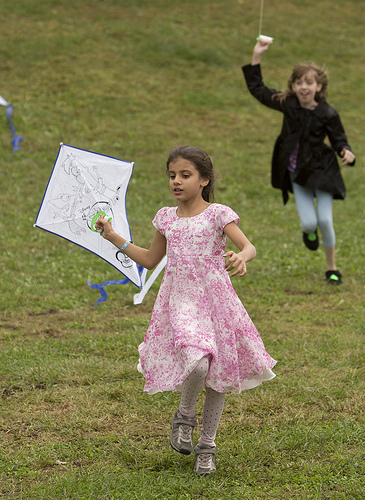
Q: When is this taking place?
A: Daylight.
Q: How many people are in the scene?
A: Two.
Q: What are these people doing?
A: Flying kites.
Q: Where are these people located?
A: Field.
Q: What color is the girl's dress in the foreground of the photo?
A: Pink and white.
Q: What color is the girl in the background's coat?
A: Black.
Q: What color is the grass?
A: Green.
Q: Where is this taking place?
A: In the park.